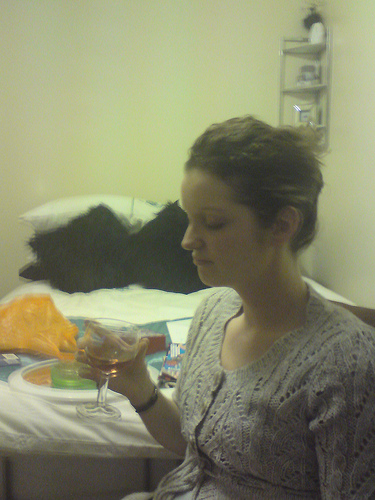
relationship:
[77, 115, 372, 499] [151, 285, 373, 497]
she wears a sweater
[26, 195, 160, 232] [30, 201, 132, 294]
pillow on top of pillow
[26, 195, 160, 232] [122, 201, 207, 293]
pillow on top of pillow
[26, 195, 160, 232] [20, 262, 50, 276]
pillow on top of pillow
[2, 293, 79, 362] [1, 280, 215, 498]
bag on bed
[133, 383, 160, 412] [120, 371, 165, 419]
watch on wrist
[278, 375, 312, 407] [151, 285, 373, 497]
holes in sweater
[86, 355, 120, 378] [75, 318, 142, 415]
wine in glass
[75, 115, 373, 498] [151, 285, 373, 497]
woman wearing a sweater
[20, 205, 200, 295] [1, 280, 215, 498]
pillows on bed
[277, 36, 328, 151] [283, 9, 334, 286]
shelf in corner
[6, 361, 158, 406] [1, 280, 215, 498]
tray on bed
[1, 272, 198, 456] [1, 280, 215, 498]
sheets on bed